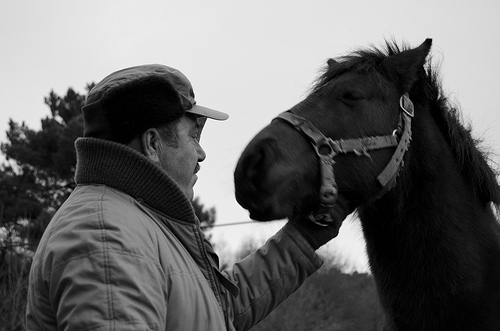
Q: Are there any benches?
A: No, there are no benches.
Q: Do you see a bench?
A: No, there are no benches.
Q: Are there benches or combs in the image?
A: No, there are no benches or combs.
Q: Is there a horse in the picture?
A: Yes, there is a horse.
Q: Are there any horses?
A: Yes, there is a horse.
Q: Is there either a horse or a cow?
A: Yes, there is a horse.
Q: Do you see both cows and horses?
A: No, there is a horse but no cows.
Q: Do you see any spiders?
A: No, there are no spiders.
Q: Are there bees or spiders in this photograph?
A: No, there are no spiders or bees.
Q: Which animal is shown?
A: The animal is a horse.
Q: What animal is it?
A: The animal is a horse.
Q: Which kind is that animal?
A: This is a horse.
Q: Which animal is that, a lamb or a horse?
A: This is a horse.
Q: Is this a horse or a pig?
A: This is a horse.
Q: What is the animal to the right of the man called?
A: The animal is a horse.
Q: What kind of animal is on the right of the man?
A: The animal is a horse.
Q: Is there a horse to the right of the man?
A: Yes, there is a horse to the right of the man.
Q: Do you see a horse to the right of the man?
A: Yes, there is a horse to the right of the man.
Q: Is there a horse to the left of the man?
A: No, the horse is to the right of the man.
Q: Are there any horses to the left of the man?
A: No, the horse is to the right of the man.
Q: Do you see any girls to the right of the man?
A: No, there is a horse to the right of the man.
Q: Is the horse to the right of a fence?
A: No, the horse is to the right of a man.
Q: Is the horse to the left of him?
A: No, the horse is to the right of the man.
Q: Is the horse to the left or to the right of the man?
A: The horse is to the right of the man.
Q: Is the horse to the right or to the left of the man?
A: The horse is to the right of the man.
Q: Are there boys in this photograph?
A: No, there are no boys.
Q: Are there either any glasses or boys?
A: No, there are no boys or glasses.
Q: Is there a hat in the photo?
A: Yes, there is a hat.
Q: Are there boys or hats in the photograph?
A: Yes, there is a hat.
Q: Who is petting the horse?
A: The man is petting the horse.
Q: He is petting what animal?
A: The man is petting the horse.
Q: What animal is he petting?
A: The man is petting the horse.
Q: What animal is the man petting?
A: The man is petting the horse.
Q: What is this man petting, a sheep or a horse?
A: The man is petting a horse.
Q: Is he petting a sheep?
A: No, the man is petting the horse.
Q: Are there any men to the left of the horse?
A: Yes, there is a man to the left of the horse.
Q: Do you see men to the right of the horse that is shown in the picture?
A: No, the man is to the left of the horse.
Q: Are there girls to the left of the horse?
A: No, there is a man to the left of the horse.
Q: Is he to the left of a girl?
A: No, the man is to the left of the horse.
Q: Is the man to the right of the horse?
A: No, the man is to the left of the horse.